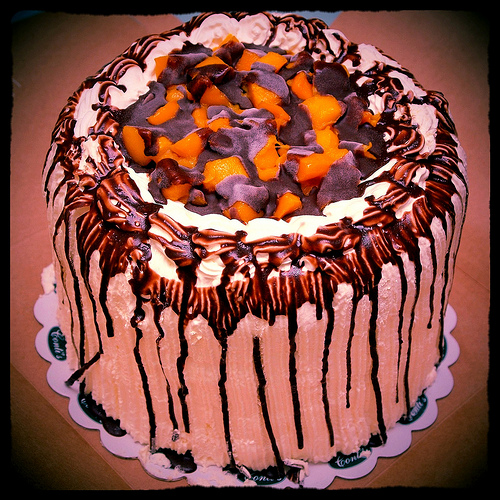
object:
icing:
[247, 216, 282, 234]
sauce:
[181, 269, 192, 281]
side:
[43, 165, 454, 471]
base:
[32, 261, 460, 488]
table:
[10, 10, 489, 491]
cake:
[42, 10, 467, 471]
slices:
[298, 90, 340, 129]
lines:
[252, 335, 284, 469]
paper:
[34, 260, 460, 487]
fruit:
[203, 155, 250, 193]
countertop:
[11, 13, 490, 490]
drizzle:
[287, 305, 304, 449]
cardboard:
[10, 226, 490, 490]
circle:
[47, 325, 68, 360]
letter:
[50, 331, 62, 336]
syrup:
[184, 42, 199, 53]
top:
[113, 34, 389, 222]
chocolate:
[169, 119, 187, 134]